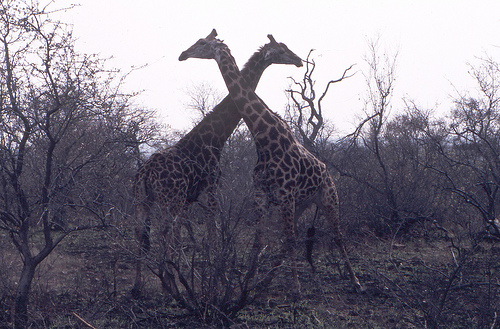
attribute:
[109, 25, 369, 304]
giraffes — fighting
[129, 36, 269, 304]
giraffe — embracing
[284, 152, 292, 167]
spot — brown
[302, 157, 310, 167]
spot — brown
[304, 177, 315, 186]
spot — brown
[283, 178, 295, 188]
spot — brown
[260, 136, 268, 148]
spot — brown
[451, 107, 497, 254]
tree — bare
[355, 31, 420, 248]
tree — bare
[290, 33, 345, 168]
tree — bare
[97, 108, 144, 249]
tree — bare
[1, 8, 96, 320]
tree — bare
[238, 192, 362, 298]
4 legs — four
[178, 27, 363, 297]
mammal — large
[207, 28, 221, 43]
ears — small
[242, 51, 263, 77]
mane — short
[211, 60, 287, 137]
neck — long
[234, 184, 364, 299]
legs — skinny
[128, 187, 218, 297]
legs — skinny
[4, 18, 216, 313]
trees — dead, leafless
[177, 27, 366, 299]
giraffe — slamming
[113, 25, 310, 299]
giraffe — small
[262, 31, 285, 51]
ear — small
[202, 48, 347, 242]
giraffe — walking